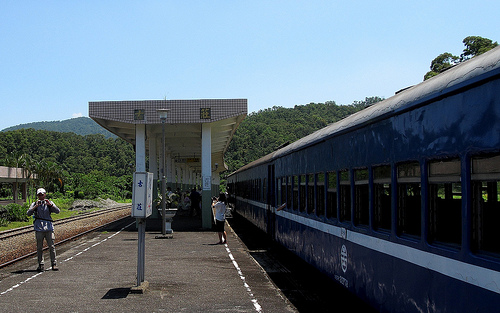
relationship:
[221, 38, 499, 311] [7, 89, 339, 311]
train at station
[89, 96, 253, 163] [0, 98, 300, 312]
covering over station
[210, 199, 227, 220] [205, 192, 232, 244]
shirt on woman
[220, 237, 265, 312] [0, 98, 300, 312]
line on station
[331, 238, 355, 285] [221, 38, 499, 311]
insignia on train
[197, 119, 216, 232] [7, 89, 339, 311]
support post at station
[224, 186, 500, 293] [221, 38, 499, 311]
stripe on train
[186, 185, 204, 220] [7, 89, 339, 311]
person on station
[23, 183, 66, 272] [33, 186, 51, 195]
man wearing cap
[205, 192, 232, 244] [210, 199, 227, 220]
woman has shirt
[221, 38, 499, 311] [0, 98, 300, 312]
train on right of station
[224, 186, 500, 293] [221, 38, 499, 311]
stripe on side of train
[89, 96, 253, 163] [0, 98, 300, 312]
covering of station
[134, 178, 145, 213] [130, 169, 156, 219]
letters on box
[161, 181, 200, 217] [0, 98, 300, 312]
people in station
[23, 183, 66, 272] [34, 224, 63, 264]
man wears pants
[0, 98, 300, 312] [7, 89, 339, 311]
station of station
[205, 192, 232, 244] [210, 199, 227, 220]
woman in shirt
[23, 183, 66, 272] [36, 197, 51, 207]
man with camera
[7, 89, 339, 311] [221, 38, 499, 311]
station for train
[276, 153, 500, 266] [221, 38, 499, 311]
windows on train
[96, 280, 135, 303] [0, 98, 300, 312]
shadow on station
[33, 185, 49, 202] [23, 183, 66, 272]
head of man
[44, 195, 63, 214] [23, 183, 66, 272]
arm of man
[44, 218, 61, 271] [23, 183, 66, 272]
leg of man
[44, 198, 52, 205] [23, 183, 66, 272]
hand of man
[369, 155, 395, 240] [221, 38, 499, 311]
window on train